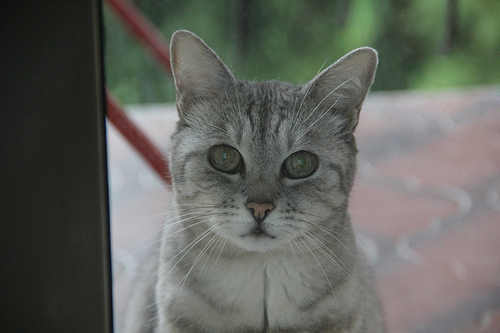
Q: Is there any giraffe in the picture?
A: No, there are no giraffes.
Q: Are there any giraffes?
A: No, there are no giraffes.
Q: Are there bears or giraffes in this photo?
A: No, there are no giraffes or bears.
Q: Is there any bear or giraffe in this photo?
A: No, there are no giraffes or bears.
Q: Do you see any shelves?
A: No, there are no shelves.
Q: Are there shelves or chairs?
A: No, there are no shelves or chairs.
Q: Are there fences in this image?
A: No, there are no fences.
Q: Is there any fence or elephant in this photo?
A: No, there are no fences or elephants.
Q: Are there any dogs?
A: No, there are no dogs.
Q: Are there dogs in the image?
A: No, there are no dogs.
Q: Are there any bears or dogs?
A: No, there are no dogs or bears.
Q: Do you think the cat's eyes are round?
A: Yes, the eyes are round.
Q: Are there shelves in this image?
A: No, there are no shelves.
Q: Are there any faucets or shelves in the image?
A: No, there are no shelves or faucets.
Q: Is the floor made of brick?
A: Yes, the floor is made of brick.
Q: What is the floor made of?
A: The floor is made of brick.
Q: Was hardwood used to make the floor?
A: No, the floor is made of brick.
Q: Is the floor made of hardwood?
A: No, the floor is made of brick.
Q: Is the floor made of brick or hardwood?
A: The floor is made of brick.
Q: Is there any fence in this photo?
A: No, there are no fences.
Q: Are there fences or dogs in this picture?
A: No, there are no fences or dogs.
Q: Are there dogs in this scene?
A: No, there are no dogs.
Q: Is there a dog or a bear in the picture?
A: No, there are no dogs or bears.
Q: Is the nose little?
A: Yes, the nose is little.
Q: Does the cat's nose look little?
A: Yes, the nose is little.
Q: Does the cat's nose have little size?
A: Yes, the nose is little.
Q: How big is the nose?
A: The nose is little.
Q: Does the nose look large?
A: No, the nose is little.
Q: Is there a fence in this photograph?
A: No, there are no fences.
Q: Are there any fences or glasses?
A: No, there are no fences or glasses.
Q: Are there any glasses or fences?
A: No, there are no fences or glasses.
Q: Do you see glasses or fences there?
A: No, there are no fences or glasses.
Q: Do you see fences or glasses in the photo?
A: No, there are no fences or glasses.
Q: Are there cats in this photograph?
A: Yes, there is a cat.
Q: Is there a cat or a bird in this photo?
A: Yes, there is a cat.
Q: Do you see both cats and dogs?
A: No, there is a cat but no dogs.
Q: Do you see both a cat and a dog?
A: No, there is a cat but no dogs.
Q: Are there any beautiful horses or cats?
A: Yes, there is a beautiful cat.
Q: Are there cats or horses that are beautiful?
A: Yes, the cat is beautiful.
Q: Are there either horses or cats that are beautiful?
A: Yes, the cat is beautiful.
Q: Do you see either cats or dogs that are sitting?
A: Yes, the cat is sitting.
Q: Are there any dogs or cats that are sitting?
A: Yes, the cat is sitting.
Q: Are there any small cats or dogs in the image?
A: Yes, there is a small cat.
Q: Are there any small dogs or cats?
A: Yes, there is a small cat.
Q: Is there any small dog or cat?
A: Yes, there is a small cat.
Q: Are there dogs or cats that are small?
A: Yes, the cat is small.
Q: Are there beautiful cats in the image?
A: Yes, there is a beautiful cat.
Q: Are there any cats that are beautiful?
A: Yes, there is a cat that is beautiful.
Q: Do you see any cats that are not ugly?
A: Yes, there is an beautiful cat.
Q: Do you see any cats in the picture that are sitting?
A: Yes, there is a cat that is sitting.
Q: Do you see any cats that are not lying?
A: Yes, there is a cat that is sitting .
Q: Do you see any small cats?
A: Yes, there is a small cat.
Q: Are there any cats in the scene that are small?
A: Yes, there is a cat that is small.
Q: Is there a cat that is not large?
A: Yes, there is a small cat.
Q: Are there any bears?
A: No, there are no bears.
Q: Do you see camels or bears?
A: No, there are no bears or camels.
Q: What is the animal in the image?
A: The animal is a cat.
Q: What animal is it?
A: The animal is a cat.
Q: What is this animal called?
A: This is a cat.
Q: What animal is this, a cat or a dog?
A: This is a cat.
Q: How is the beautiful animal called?
A: The animal is a cat.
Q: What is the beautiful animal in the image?
A: The animal is a cat.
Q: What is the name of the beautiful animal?
A: The animal is a cat.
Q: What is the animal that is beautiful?
A: The animal is a cat.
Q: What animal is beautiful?
A: The animal is a cat.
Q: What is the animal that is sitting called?
A: The animal is a cat.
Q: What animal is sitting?
A: The animal is a cat.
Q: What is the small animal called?
A: The animal is a cat.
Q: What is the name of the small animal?
A: The animal is a cat.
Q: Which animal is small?
A: The animal is a cat.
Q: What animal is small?
A: The animal is a cat.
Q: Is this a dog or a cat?
A: This is a cat.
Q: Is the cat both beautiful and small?
A: Yes, the cat is beautiful and small.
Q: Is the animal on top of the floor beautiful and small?
A: Yes, the cat is beautiful and small.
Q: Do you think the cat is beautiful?
A: Yes, the cat is beautiful.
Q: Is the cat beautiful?
A: Yes, the cat is beautiful.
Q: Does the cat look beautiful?
A: Yes, the cat is beautiful.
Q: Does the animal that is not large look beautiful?
A: Yes, the cat is beautiful.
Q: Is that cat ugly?
A: No, the cat is beautiful.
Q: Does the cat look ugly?
A: No, the cat is beautiful.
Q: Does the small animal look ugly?
A: No, the cat is beautiful.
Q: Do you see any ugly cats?
A: No, there is a cat but it is beautiful.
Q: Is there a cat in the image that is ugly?
A: No, there is a cat but it is beautiful.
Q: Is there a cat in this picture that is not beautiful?
A: No, there is a cat but it is beautiful.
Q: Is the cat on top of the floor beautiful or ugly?
A: The cat is beautiful.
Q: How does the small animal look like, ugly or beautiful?
A: The cat is beautiful.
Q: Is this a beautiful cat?
A: Yes, this is a beautiful cat.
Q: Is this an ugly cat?
A: No, this is a beautiful cat.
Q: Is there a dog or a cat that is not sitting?
A: No, there is a cat but it is sitting.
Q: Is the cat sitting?
A: Yes, the cat is sitting.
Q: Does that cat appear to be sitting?
A: Yes, the cat is sitting.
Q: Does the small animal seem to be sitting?
A: Yes, the cat is sitting.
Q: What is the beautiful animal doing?
A: The cat is sitting.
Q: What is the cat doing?
A: The cat is sitting.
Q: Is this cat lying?
A: No, the cat is sitting.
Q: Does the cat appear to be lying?
A: No, the cat is sitting.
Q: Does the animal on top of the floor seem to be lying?
A: No, the cat is sitting.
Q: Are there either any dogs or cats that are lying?
A: No, there is a cat but it is sitting.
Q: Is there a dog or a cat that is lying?
A: No, there is a cat but it is sitting.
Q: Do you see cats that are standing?
A: No, there is a cat but it is sitting.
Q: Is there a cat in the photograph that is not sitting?
A: No, there is a cat but it is sitting.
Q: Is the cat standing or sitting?
A: The cat is sitting.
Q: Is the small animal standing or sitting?
A: The cat is sitting.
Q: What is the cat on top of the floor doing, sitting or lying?
A: The cat is sitting.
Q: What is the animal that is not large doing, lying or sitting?
A: The cat is sitting.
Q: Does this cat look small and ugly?
A: No, the cat is small but beautiful.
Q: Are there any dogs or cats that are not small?
A: No, there is a cat but it is small.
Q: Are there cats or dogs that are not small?
A: No, there is a cat but it is small.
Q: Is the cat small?
A: Yes, the cat is small.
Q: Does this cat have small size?
A: Yes, the cat is small.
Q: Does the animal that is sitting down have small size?
A: Yes, the cat is small.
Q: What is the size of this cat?
A: The cat is small.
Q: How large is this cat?
A: The cat is small.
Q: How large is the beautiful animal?
A: The cat is small.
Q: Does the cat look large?
A: No, the cat is small.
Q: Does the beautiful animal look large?
A: No, the cat is small.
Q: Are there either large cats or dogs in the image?
A: No, there is a cat but it is small.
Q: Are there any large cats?
A: No, there is a cat but it is small.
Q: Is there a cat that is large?
A: No, there is a cat but it is small.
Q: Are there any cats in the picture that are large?
A: No, there is a cat but it is small.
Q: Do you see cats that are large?
A: No, there is a cat but it is small.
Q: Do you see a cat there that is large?
A: No, there is a cat but it is small.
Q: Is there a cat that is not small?
A: No, there is a cat but it is small.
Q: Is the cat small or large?
A: The cat is small.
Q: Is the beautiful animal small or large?
A: The cat is small.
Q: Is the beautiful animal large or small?
A: The cat is small.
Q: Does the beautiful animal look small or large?
A: The cat is small.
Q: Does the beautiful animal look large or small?
A: The cat is small.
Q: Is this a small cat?
A: Yes, this is a small cat.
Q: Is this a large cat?
A: No, this is a small cat.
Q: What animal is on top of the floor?
A: The cat is on top of the floor.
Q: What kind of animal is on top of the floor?
A: The animal is a cat.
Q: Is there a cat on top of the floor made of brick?
A: Yes, there is a cat on top of the floor.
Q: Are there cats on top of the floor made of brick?
A: Yes, there is a cat on top of the floor.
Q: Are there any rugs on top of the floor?
A: No, there is a cat on top of the floor.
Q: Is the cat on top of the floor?
A: Yes, the cat is on top of the floor.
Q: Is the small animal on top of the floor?
A: Yes, the cat is on top of the floor.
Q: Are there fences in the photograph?
A: No, there are no fences.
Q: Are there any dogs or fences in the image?
A: No, there are no fences or dogs.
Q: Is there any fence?
A: No, there are no fences.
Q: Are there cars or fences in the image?
A: No, there are no fences or cars.